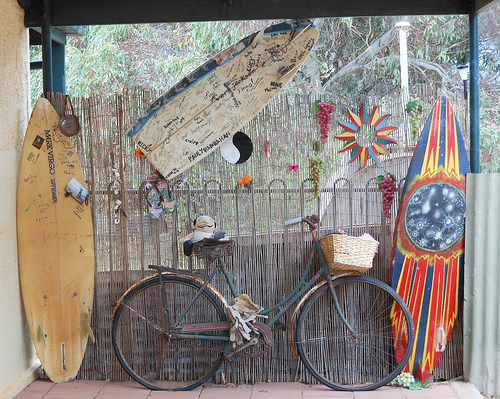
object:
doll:
[180, 214, 227, 256]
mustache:
[197, 223, 212, 227]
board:
[388, 92, 471, 384]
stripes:
[410, 96, 470, 177]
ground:
[467, 140, 481, 156]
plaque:
[333, 103, 399, 169]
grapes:
[380, 177, 398, 218]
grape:
[316, 99, 334, 143]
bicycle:
[110, 214, 415, 391]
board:
[16, 97, 96, 384]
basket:
[319, 231, 381, 272]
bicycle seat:
[190, 236, 238, 259]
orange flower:
[235, 172, 254, 186]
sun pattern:
[334, 103, 398, 169]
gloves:
[228, 305, 256, 332]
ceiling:
[19, 1, 473, 27]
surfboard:
[127, 16, 321, 182]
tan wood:
[17, 98, 97, 387]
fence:
[40, 83, 472, 384]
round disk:
[219, 130, 254, 164]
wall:
[1, 0, 43, 398]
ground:
[15, 365, 485, 398]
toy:
[179, 214, 227, 256]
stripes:
[392, 252, 460, 380]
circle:
[403, 182, 466, 253]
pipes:
[267, 177, 290, 381]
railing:
[83, 176, 408, 383]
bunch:
[309, 157, 324, 201]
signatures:
[186, 178, 232, 212]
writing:
[263, 80, 285, 93]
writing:
[27, 152, 42, 164]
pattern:
[397, 168, 468, 259]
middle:
[392, 162, 472, 272]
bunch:
[317, 99, 336, 144]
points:
[335, 103, 397, 167]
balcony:
[0, 0, 495, 398]